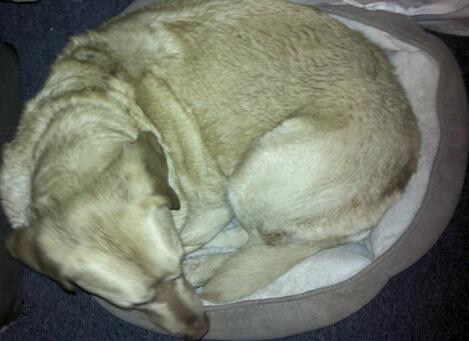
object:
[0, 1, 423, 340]
dog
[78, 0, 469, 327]
bed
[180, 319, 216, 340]
nose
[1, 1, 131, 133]
carpet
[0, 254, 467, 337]
carpet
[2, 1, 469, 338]
floor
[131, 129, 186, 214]
ear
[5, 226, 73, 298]
ear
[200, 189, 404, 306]
tail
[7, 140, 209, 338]
head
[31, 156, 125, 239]
top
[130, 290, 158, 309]
eyelids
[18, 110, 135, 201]
neck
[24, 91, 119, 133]
nape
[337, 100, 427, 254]
butt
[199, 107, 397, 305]
legs